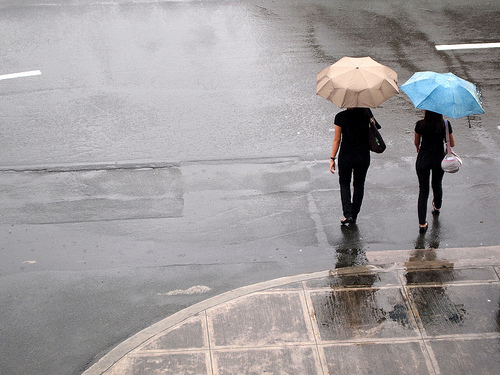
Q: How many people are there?
A: Two.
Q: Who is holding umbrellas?
A: The women.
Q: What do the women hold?
A: Umbrellas.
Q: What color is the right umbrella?
A: Blue.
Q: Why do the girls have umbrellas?
A: It's raining.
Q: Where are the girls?
A: On the sidewalk.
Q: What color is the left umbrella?
A: Beige.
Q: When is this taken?
A: During the daytime.